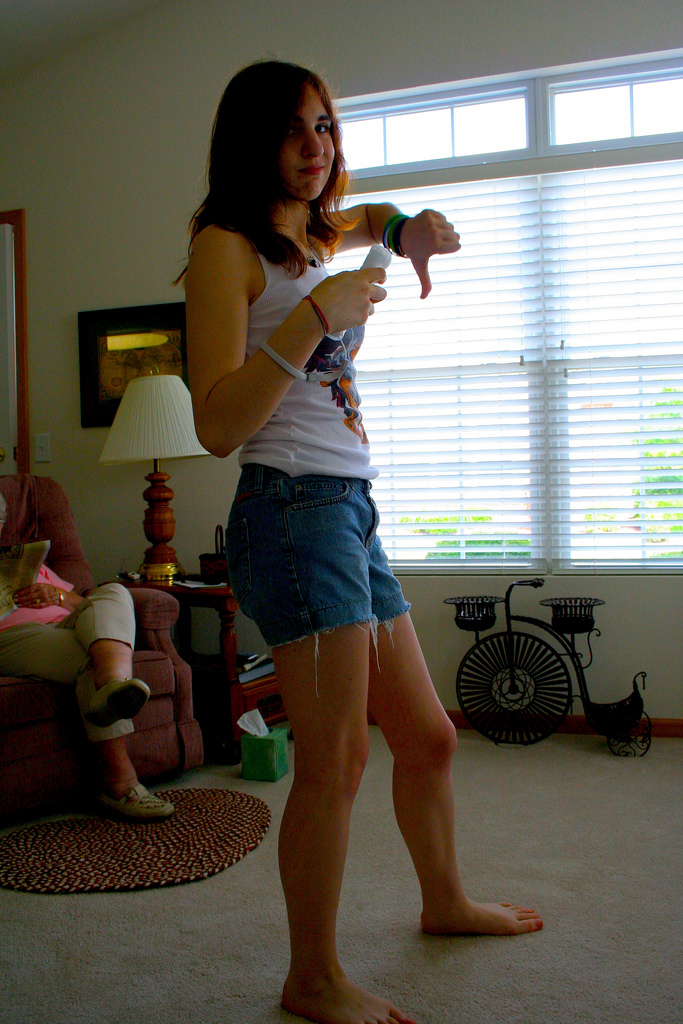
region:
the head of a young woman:
[243, 61, 373, 226]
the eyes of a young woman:
[261, 112, 348, 162]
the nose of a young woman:
[279, 114, 349, 168]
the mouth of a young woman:
[273, 149, 360, 219]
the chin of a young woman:
[288, 163, 364, 223]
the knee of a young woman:
[267, 717, 423, 816]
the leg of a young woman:
[263, 518, 409, 996]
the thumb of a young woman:
[390, 247, 448, 297]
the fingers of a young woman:
[320, 241, 421, 358]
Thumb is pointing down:
[413, 251, 435, 301]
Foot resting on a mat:
[104, 777, 179, 825]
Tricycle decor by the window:
[444, 572, 657, 758]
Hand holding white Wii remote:
[302, 267, 384, 335]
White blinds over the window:
[309, 157, 681, 569]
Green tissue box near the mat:
[229, 703, 290, 783]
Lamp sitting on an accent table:
[99, 367, 215, 574]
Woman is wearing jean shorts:
[185, 53, 546, 1022]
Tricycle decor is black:
[441, 568, 657, 759]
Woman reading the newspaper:
[0, 491, 179, 817]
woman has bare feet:
[187, 58, 549, 1021]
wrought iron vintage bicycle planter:
[437, 567, 656, 761]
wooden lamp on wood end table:
[96, 368, 297, 769]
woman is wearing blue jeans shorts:
[179, 49, 559, 1022]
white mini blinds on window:
[320, 64, 676, 580]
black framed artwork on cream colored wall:
[3, 6, 681, 740]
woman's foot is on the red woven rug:
[2, 475, 276, 896]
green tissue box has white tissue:
[234, 706, 290, 785]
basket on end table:
[104, 519, 299, 775]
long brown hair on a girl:
[161, 57, 366, 282]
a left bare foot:
[421, 888, 544, 941]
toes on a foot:
[507, 897, 542, 931]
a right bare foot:
[272, 964, 410, 1018]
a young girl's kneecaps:
[337, 723, 459, 772]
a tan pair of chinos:
[66, 584, 156, 738]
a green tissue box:
[234, 708, 288, 773]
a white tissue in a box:
[237, 703, 264, 735]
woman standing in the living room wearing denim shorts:
[185, 52, 544, 1020]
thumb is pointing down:
[408, 248, 433, 302]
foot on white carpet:
[415, 882, 539, 938]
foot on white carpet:
[277, 969, 415, 1022]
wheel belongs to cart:
[457, 630, 569, 744]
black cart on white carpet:
[441, 574, 657, 760]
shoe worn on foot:
[91, 774, 171, 824]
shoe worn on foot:
[84, 673, 145, 728]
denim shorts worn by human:
[221, 454, 408, 645]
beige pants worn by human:
[5, 582, 135, 740]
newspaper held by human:
[0, 538, 51, 608]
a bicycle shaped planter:
[459, 577, 655, 757]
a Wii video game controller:
[325, 241, 390, 340]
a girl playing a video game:
[176, 55, 543, 1022]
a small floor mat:
[2, 783, 272, 892]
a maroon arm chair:
[4, 475, 202, 802]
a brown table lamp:
[97, 370, 211, 583]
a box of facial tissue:
[235, 707, 289, 781]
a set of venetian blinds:
[323, 157, 680, 567]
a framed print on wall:
[74, 299, 191, 429]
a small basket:
[199, 517, 233, 583]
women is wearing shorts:
[250, 504, 363, 599]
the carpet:
[485, 959, 565, 1010]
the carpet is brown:
[485, 953, 540, 990]